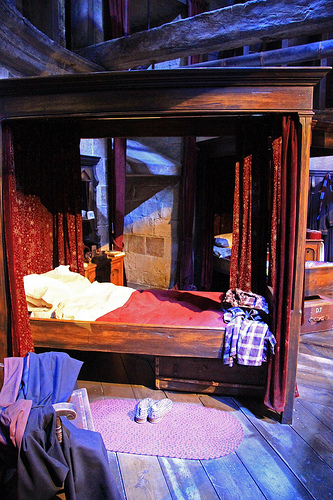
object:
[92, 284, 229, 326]
red blanket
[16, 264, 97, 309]
pillow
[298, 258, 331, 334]
rack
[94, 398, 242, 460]
rug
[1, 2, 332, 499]
set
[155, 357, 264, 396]
trunk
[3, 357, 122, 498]
clothes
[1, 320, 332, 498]
floor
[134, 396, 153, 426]
shoes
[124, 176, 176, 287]
wall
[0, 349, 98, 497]
chair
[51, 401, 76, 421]
arm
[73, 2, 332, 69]
beam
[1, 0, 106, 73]
beam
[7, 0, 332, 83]
ceiling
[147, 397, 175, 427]
shoes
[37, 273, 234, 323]
sheet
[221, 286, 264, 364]
robe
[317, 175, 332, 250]
clothes hanging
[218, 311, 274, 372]
shirt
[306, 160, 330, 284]
closet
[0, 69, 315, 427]
bed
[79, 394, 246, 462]
mat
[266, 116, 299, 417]
curtain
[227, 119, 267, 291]
curtain